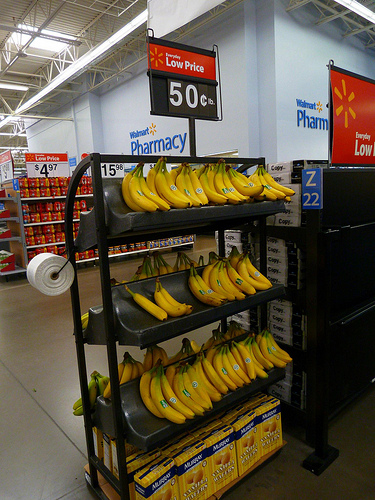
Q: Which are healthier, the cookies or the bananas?
A: The bananas are healthier than the cookies.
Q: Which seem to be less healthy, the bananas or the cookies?
A: The cookies are less healthy than the bananas.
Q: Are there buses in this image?
A: No, there are no buses.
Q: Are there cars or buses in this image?
A: No, there are no buses or cars.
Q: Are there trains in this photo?
A: No, there are no trains.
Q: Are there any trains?
A: No, there are no trains.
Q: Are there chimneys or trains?
A: No, there are no trains or chimneys.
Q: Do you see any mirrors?
A: No, there are no mirrors.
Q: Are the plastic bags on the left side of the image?
A: Yes, the bags are on the left of the image.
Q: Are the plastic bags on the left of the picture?
A: Yes, the bags are on the left of the image.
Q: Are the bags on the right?
A: No, the bags are on the left of the image.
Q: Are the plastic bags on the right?
A: No, the bags are on the left of the image.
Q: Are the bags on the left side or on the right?
A: The bags are on the left of the image.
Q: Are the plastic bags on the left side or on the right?
A: The bags are on the left of the image.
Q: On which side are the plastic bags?
A: The bags are on the left of the image.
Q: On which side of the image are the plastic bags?
A: The bags are on the left of the image.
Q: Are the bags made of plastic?
A: Yes, the bags are made of plastic.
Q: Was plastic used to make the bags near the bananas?
A: Yes, the bags are made of plastic.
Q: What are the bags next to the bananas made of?
A: The bags are made of plastic.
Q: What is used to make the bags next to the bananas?
A: The bags are made of plastic.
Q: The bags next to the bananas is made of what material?
A: The bags are made of plastic.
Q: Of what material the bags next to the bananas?
A: The bags are made of plastic.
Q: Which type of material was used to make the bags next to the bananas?
A: The bags are made of plastic.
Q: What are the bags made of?
A: The bags are made of plastic.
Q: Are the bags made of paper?
A: No, the bags are made of plastic.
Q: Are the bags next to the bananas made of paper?
A: No, the bags are made of plastic.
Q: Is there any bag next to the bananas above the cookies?
A: Yes, there are bags next to the bananas.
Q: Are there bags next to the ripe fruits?
A: Yes, there are bags next to the bananas.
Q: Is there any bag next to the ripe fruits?
A: Yes, there are bags next to the bananas.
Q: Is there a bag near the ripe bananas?
A: Yes, there are bags near the bananas.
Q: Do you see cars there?
A: No, there are no cars.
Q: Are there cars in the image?
A: No, there are no cars.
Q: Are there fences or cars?
A: No, there are no cars or fences.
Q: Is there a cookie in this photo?
A: Yes, there are cookies.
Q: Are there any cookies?
A: Yes, there are cookies.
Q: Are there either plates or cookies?
A: Yes, there are cookies.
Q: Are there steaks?
A: No, there are no steaks.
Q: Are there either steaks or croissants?
A: No, there are no steaks or croissants.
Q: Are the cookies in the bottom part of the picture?
A: Yes, the cookies are in the bottom of the image.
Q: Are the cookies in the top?
A: No, the cookies are in the bottom of the image.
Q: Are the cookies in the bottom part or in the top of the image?
A: The cookies are in the bottom of the image.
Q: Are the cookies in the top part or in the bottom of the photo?
A: The cookies are in the bottom of the image.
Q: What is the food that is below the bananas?
A: The food is cookies.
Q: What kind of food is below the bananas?
A: The food is cookies.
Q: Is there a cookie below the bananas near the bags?
A: Yes, there are cookies below the bananas.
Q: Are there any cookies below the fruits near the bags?
A: Yes, there are cookies below the bananas.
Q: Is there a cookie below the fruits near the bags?
A: Yes, there are cookies below the bananas.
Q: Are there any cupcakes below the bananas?
A: No, there are cookies below the bananas.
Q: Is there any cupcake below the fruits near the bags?
A: No, there are cookies below the bananas.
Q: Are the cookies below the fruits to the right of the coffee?
A: Yes, the cookies are below the bananas.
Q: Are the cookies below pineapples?
A: No, the cookies are below the bananas.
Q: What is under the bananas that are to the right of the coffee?
A: The cookies are under the bananas.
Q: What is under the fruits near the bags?
A: The cookies are under the bananas.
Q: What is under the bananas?
A: The cookies are under the bananas.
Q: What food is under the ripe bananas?
A: The food is cookies.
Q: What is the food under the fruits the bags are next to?
A: The food is cookies.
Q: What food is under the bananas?
A: The food is cookies.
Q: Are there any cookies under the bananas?
A: Yes, there are cookies under the bananas.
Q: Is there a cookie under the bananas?
A: Yes, there are cookies under the bananas.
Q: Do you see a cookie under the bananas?
A: Yes, there are cookies under the bananas.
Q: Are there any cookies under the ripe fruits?
A: Yes, there are cookies under the bananas.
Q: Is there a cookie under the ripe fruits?
A: Yes, there are cookies under the bananas.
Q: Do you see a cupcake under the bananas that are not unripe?
A: No, there are cookies under the bananas.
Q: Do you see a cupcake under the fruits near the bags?
A: No, there are cookies under the bananas.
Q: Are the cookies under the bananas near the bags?
A: Yes, the cookies are under the bananas.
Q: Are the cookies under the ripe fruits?
A: Yes, the cookies are under the bananas.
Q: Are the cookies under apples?
A: No, the cookies are under the bananas.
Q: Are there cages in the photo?
A: No, there are no cages.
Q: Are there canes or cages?
A: No, there are no cages or canes.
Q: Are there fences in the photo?
A: No, there are no fences.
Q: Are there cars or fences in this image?
A: No, there are no fences or cars.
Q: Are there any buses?
A: No, there are no buses.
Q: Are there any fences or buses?
A: No, there are no buses or fences.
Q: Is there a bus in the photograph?
A: No, there are no buses.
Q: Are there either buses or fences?
A: No, there are no buses or fences.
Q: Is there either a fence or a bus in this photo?
A: No, there are no buses or fences.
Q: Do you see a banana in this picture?
A: Yes, there are bananas.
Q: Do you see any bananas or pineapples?
A: Yes, there are bananas.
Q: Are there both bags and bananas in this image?
A: Yes, there are both bananas and a bag.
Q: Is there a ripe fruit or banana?
A: Yes, there are ripe bananas.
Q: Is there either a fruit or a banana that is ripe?
A: Yes, the bananas are ripe.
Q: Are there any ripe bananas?
A: Yes, there are ripe bananas.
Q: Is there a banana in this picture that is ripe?
A: Yes, there are bananas that are ripe.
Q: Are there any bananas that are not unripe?
A: Yes, there are ripe bananas.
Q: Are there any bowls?
A: No, there are no bowls.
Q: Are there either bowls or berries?
A: No, there are no bowls or berries.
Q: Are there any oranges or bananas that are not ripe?
A: No, there are bananas but they are ripe.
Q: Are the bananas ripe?
A: Yes, the bananas are ripe.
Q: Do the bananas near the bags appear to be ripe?
A: Yes, the bananas are ripe.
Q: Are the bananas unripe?
A: No, the bananas are ripe.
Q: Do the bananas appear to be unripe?
A: No, the bananas are ripe.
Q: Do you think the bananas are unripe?
A: No, the bananas are ripe.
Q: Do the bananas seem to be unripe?
A: No, the bananas are ripe.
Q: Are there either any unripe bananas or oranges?
A: No, there are bananas but they are ripe.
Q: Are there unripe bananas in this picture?
A: No, there are bananas but they are ripe.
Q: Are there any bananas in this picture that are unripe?
A: No, there are bananas but they are ripe.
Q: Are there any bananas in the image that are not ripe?
A: No, there are bananas but they are ripe.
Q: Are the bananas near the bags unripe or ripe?
A: The bananas are ripe.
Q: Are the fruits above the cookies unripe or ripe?
A: The bananas are ripe.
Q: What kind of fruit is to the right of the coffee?
A: The fruits are bananas.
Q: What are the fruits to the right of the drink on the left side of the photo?
A: The fruits are bananas.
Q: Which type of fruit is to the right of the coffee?
A: The fruits are bananas.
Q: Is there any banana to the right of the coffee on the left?
A: Yes, there are bananas to the right of the coffee.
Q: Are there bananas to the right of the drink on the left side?
A: Yes, there are bananas to the right of the coffee.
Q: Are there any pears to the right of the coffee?
A: No, there are bananas to the right of the coffee.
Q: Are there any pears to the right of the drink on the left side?
A: No, there are bananas to the right of the coffee.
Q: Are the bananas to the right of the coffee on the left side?
A: Yes, the bananas are to the right of the coffee.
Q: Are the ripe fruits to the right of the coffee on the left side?
A: Yes, the bananas are to the right of the coffee.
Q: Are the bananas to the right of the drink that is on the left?
A: Yes, the bananas are to the right of the coffee.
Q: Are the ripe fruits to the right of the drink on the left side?
A: Yes, the bananas are to the right of the coffee.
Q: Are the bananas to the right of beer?
A: No, the bananas are to the right of the coffee.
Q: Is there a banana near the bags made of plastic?
A: Yes, there are bananas near the bags.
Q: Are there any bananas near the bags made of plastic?
A: Yes, there are bananas near the bags.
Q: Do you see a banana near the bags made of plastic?
A: Yes, there are bananas near the bags.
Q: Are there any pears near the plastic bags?
A: No, there are bananas near the bags.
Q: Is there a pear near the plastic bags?
A: No, there are bananas near the bags.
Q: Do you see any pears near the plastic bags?
A: No, there are bananas near the bags.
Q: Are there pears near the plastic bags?
A: No, there are bananas near the bags.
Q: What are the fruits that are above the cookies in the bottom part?
A: The fruits are bananas.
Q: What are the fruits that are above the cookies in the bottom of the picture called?
A: The fruits are bananas.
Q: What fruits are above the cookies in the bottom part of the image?
A: The fruits are bananas.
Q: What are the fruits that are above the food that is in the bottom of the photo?
A: The fruits are bananas.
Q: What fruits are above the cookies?
A: The fruits are bananas.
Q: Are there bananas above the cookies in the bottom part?
A: Yes, there are bananas above the cookies.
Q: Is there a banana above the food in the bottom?
A: Yes, there are bananas above the cookies.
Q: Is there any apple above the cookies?
A: No, there are bananas above the cookies.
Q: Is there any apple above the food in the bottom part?
A: No, there are bananas above the cookies.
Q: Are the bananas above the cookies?
A: Yes, the bananas are above the cookies.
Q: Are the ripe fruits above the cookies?
A: Yes, the bananas are above the cookies.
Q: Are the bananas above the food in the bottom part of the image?
A: Yes, the bananas are above the cookies.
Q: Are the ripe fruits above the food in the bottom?
A: Yes, the bananas are above the cookies.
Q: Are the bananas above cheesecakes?
A: No, the bananas are above the cookies.